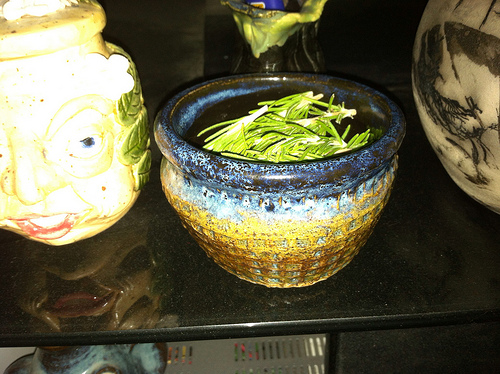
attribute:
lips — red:
[20, 204, 88, 246]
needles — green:
[201, 90, 373, 157]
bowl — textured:
[168, 62, 417, 309]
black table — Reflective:
[2, 5, 498, 349]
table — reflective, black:
[6, 232, 498, 344]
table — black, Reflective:
[152, 273, 495, 335]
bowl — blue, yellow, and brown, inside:
[140, 70, 415, 288]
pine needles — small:
[199, 104, 361, 159]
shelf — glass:
[0, 0, 499, 343]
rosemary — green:
[206, 77, 380, 178]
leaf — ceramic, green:
[240, 3, 356, 70]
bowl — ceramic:
[154, 72, 404, 289]